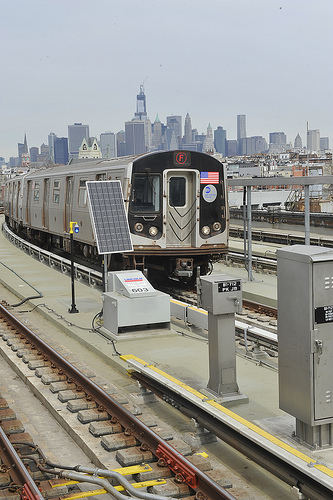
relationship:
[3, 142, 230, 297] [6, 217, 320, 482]
commuter train on tracks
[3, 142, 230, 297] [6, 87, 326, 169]
commuter train outside large city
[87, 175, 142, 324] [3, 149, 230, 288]
solar panel used to power commuter train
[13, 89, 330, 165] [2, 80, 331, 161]
cityscape with man tall buildings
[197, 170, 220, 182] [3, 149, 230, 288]
american flag on end of commuter train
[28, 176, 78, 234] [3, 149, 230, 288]
doors on commuter train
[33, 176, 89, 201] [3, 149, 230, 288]
windows on commuter train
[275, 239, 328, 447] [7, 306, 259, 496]
electrical box next to tracks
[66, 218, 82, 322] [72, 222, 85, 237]
thin pole with blue light